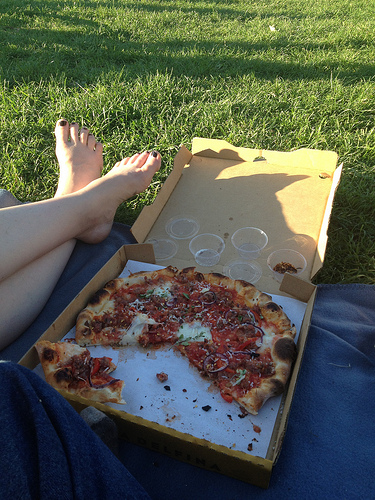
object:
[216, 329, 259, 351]
onions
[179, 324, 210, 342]
cheese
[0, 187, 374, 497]
blanket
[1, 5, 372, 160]
grass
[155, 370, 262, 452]
crumbs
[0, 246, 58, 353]
leg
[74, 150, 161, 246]
feet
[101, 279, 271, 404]
topping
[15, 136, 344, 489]
box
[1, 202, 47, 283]
leg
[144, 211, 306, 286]
container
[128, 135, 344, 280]
lids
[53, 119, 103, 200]
feet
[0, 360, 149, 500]
denim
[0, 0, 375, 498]
field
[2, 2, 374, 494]
ground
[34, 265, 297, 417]
pizza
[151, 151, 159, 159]
toenails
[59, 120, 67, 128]
toenails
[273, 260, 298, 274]
seasoning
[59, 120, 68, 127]
nail polish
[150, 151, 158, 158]
nail polish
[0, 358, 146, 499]
person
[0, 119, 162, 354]
female